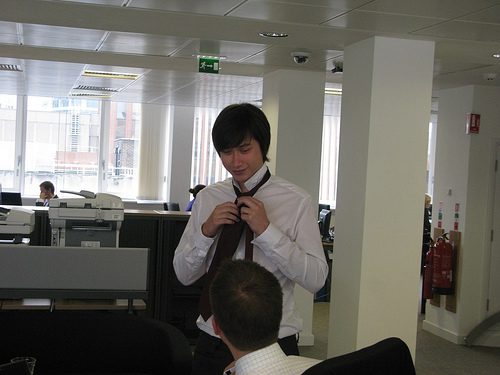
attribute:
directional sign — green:
[197, 57, 222, 74]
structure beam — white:
[323, 33, 441, 357]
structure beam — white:
[256, 60, 331, 348]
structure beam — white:
[161, 93, 193, 218]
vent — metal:
[66, 80, 119, 96]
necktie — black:
[203, 178, 256, 288]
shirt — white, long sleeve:
[165, 159, 330, 348]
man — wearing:
[174, 106, 436, 374]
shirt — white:
[171, 177, 343, 277]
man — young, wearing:
[173, 100, 328, 372]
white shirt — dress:
[171, 160, 329, 340]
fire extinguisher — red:
[426, 229, 460, 299]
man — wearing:
[156, 81, 361, 348]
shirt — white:
[132, 180, 334, 295]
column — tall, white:
[337, 35, 439, 344]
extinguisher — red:
[421, 230, 459, 310]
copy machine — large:
[44, 193, 130, 245]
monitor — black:
[319, 204, 331, 236]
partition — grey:
[3, 254, 203, 311]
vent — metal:
[35, 47, 177, 152]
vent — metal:
[71, 63, 156, 101]